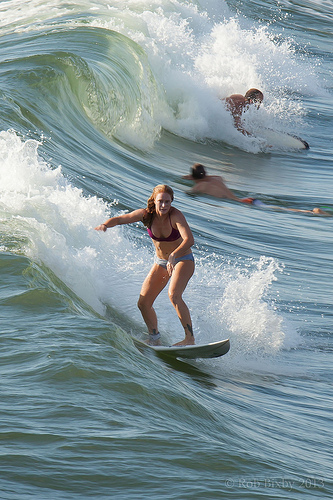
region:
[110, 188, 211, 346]
woman surfer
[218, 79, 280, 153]
male surfer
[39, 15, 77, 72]
white and green ocean waves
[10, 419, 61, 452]
white and green ocean waves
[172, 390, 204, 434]
white and green ocean waves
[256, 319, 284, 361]
white and green ocean waves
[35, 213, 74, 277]
white and green ocean waves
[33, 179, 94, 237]
white and green ocean waves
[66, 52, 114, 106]
white and green ocean waves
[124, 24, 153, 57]
white and green ocean waves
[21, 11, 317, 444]
Surfers riding the waves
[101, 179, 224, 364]
A riding a surfboard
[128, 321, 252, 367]
A white surfboard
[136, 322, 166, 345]
A safety ankle strap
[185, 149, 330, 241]
A man paddling out to surf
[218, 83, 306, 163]
A man getting up on a surfboard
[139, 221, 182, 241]
A purple bathing suit top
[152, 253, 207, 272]
A blue bathing suit bottom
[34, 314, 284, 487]
Blue green wavy water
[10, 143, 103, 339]
White foam on the wave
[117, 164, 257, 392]
the girl is on the surfborad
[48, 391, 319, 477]
the water is greenish blue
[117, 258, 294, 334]
the girl is not wearing pants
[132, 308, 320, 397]
the surfboard is white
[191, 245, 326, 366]
the water is splashing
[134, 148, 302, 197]
the man is swimming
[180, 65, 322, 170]
the man is surfing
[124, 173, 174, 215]
the girl has light colored hair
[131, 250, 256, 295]
the lady is wearing blue shorts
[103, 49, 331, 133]
the wave is over the man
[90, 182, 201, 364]
woman wearing bikini and surfing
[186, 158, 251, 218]
man in water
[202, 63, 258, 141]
man n water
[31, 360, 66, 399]
white and green ocean waves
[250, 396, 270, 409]
white and green ocean waves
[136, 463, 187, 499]
white and green ocean waves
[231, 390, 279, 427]
white and green ocean waves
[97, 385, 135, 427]
white and green ocean waves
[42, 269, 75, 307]
white and green ocean waves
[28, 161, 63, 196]
white and green ocean waves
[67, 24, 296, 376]
the people are surfing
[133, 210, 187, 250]
woman wearing bikini top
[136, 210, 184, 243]
woman's bikini top is purple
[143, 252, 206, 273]
woman wearing a bikini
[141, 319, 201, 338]
woman has tattoos on legs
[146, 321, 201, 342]
the tattoos are black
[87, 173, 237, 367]
woman standing on surfboard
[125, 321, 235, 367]
the surfboard is white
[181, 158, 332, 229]
man laying on surfboard in water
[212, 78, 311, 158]
person being splashed by wave